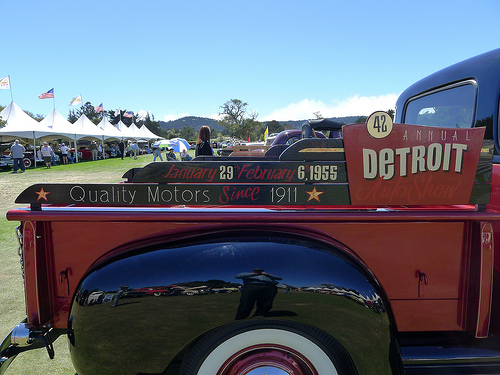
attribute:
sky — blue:
[4, 2, 484, 121]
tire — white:
[176, 320, 354, 374]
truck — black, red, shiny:
[0, 48, 499, 375]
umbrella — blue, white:
[167, 137, 190, 154]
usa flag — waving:
[37, 87, 55, 99]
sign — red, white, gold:
[342, 110, 486, 201]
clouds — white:
[261, 92, 397, 121]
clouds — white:
[135, 107, 225, 123]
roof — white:
[1, 102, 39, 137]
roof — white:
[37, 109, 74, 137]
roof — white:
[73, 112, 98, 137]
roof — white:
[95, 117, 115, 139]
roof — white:
[115, 121, 129, 137]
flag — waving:
[92, 103, 104, 113]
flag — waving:
[123, 110, 133, 118]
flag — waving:
[37, 87, 54, 99]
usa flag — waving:
[95, 103, 103, 113]